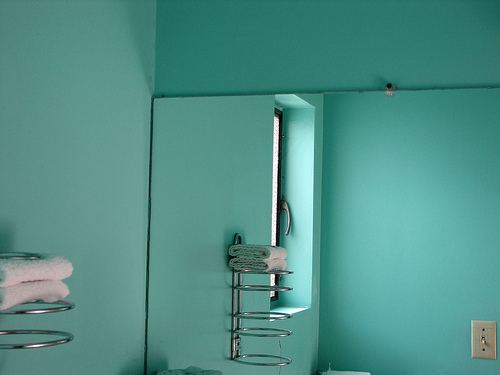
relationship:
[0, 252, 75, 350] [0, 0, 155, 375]
towel rack on wall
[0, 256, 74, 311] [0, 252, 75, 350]
towels on towel rack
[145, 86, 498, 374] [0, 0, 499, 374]
mirror in bathroom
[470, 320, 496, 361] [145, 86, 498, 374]
light switch in mirror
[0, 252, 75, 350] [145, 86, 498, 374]
towel rack in mirror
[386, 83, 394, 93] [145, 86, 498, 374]
screw holding mirror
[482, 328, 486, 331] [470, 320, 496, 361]
bolt on light switch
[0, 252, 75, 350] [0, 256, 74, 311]
towel rack has towels